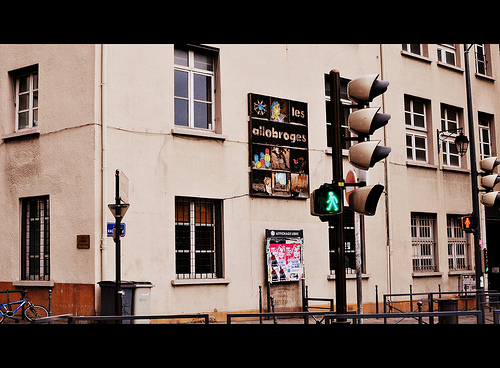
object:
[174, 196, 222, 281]
window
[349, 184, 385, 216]
light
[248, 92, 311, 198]
colorful sign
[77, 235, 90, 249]
plaque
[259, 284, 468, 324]
poles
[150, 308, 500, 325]
sidewalk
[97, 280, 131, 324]
trash bin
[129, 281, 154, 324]
trash bin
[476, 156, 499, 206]
traffic lights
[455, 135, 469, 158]
lantern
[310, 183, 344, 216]
light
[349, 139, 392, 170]
light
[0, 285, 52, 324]
bicycle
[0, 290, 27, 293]
rail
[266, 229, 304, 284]
community board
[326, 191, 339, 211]
green sign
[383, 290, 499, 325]
rails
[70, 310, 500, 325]
rail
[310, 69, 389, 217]
traffic light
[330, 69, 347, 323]
pole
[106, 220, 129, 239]
sign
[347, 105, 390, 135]
traffic light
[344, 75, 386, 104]
light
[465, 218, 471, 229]
light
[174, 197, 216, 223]
blinds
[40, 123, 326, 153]
wiring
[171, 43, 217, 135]
window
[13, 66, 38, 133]
window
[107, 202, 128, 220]
triangular sign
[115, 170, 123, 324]
pole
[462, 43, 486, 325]
pole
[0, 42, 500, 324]
building